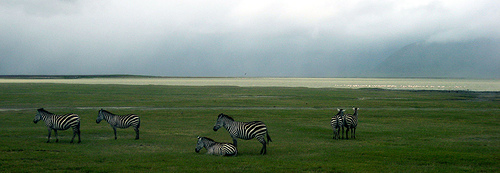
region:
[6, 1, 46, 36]
white clouds in blue sky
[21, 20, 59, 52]
white clouds in blue sky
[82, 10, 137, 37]
white clouds in blue sky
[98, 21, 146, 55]
white clouds in blue sky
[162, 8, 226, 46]
white clouds in blue sky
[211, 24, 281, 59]
white clouds in blue sky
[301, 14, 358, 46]
white clouds in blue sky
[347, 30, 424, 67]
white clouds in blue sky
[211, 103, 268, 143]
striped zebra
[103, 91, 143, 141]
striped zebra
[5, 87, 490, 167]
zebras on wide grassy area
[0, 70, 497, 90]
long body of silver water shining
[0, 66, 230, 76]
low land on other side of water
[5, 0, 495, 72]
bright clouds and blue-gray skies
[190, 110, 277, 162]
zebra laying under head of standing zebra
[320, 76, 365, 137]
a pair of zebras looking toward the water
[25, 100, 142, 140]
a walking zebra in front of a standing zebra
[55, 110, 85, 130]
wide stripes over rear of zebra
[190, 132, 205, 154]
bottom of head resting on grass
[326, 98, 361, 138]
zebras standing side by side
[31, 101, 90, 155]
black and white striped aebra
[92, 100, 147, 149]
black and white striped aebra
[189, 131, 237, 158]
black and white striped aebra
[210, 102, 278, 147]
black and white striped aebra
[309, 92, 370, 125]
black and white striped aebra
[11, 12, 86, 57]
white clouds in blue sky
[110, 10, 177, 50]
white clouds in blue sky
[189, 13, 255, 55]
white clouds in blue sky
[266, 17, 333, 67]
white clouds in blue sky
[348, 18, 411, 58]
white clouds in blue sky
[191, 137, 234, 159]
zebra on the grass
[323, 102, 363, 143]
two zebras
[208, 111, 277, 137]
a zebra standing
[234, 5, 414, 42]
white clouds in the sky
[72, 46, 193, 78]
the sky is clear and blue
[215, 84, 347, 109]
the green grass field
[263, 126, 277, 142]
tail of the zebra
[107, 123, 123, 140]
the zebra leg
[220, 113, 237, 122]
the zebras hair is black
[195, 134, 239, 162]
the zebra is laying on the gras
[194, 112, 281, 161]
Zebras in the photo.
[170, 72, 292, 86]
A water body in the photo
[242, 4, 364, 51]
Clouds in the photo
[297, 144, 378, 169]
Grass in the photo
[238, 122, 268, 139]
Black and white stripes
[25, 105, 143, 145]
Two zebras standing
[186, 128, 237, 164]
A zebra lying on the ground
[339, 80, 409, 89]
Birds in the lake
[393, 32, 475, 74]
Hills in the background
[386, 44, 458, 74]
Trees on the hill